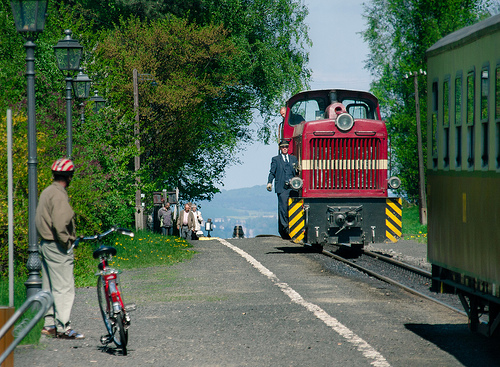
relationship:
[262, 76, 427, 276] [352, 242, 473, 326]
red train on tracks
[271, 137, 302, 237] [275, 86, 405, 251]
man standing on red train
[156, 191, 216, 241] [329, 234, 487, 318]
people walking by tracks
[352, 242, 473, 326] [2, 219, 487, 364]
tracks embedded in asphalt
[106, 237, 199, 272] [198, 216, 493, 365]
yellow flowers next to road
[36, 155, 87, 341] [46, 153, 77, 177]
man wearing helmet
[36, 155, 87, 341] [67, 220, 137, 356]
man holding bike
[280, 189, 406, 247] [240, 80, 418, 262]
caution sign on engine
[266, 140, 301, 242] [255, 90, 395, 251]
man hanging on train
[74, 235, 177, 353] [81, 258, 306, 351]
red bicycle parked on pavement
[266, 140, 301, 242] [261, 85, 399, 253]
man standing outside engine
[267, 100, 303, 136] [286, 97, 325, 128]
man's head emerging from window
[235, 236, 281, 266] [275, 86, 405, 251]
ground descends from behind red train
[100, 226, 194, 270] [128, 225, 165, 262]
flowers dotting dotting grass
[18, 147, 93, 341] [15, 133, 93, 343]
man standing beside beside a bicycle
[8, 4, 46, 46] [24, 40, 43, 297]
lamp on metal light post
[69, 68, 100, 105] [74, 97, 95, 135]
lamp on post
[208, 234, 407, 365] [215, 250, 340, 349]
white line on pavement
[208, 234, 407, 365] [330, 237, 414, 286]
white line near tracks